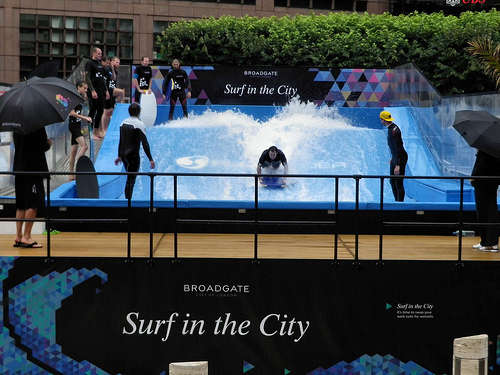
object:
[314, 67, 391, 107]
decoration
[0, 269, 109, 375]
decoration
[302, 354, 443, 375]
decoration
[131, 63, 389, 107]
sign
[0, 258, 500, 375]
sign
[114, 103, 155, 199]
person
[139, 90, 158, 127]
surfboard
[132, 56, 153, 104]
man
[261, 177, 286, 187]
surfboard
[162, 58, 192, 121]
people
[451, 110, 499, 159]
umbrella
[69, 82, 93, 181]
person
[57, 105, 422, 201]
surf pool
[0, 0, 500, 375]
city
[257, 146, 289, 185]
man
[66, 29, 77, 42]
window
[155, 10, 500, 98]
bushes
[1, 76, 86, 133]
umbrella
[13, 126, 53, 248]
man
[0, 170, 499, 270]
black fencing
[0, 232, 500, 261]
flooring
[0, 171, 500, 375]
platform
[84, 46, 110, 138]
spectator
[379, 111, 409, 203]
person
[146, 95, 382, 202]
water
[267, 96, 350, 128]
waves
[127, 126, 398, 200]
slide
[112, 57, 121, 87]
person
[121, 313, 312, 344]
advertisement